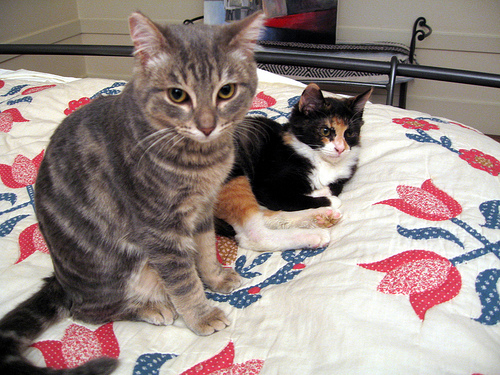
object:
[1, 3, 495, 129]
wall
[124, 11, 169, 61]
ear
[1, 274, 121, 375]
tail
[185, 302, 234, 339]
paw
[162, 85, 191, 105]
eye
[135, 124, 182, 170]
whiskers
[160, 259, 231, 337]
leg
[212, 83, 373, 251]
cat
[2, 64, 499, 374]
blanket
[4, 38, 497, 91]
pole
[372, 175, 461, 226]
flower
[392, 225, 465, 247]
stem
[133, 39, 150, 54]
hair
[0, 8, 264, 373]
cat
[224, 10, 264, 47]
ear